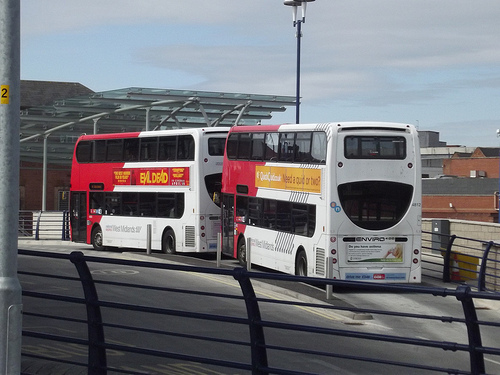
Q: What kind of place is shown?
A: It is a street.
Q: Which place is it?
A: It is a street.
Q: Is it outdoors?
A: Yes, it is outdoors.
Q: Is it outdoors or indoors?
A: It is outdoors.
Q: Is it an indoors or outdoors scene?
A: It is outdoors.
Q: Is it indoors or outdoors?
A: It is outdoors.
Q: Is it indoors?
A: No, it is outdoors.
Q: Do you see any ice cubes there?
A: No, there are no ice cubes.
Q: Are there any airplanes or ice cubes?
A: No, there are no ice cubes or airplanes.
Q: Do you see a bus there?
A: Yes, there is a bus.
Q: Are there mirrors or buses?
A: Yes, there is a bus.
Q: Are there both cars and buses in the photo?
A: No, there is a bus but no cars.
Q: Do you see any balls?
A: No, there are no balls.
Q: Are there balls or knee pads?
A: No, there are no balls or knee pads.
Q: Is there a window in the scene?
A: Yes, there are windows.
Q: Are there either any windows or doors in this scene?
A: Yes, there are windows.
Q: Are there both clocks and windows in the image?
A: No, there are windows but no clocks.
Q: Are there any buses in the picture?
A: Yes, there is a bus.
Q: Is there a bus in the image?
A: Yes, there is a bus.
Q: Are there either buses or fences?
A: Yes, there is a bus.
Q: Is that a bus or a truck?
A: That is a bus.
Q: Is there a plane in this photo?
A: No, there are no airplanes.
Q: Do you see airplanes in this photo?
A: No, there are no airplanes.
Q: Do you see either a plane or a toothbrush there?
A: No, there are no airplanes or toothbrushes.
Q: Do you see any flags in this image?
A: No, there are no flags.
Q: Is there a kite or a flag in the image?
A: No, there are no flags or kites.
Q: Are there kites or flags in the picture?
A: No, there are no flags or kites.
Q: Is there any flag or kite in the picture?
A: No, there are no flags or kites.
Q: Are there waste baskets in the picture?
A: No, there are no waste baskets.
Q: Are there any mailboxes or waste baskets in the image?
A: No, there are no waste baskets or mailboxes.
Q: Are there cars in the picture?
A: No, there are no cars.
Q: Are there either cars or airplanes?
A: No, there are no cars or airplanes.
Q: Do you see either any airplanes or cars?
A: No, there are no cars or airplanes.